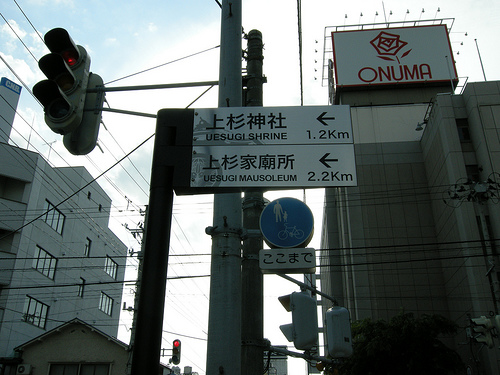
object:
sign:
[190, 105, 358, 187]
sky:
[78, 0, 207, 47]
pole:
[130, 108, 177, 375]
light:
[172, 339, 181, 365]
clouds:
[264, 1, 297, 100]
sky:
[253, 0, 495, 63]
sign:
[278, 291, 319, 350]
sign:
[261, 198, 313, 246]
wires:
[315, 239, 500, 267]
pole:
[206, 0, 240, 375]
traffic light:
[278, 291, 319, 350]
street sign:
[190, 102, 358, 187]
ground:
[145, 359, 153, 375]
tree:
[323, 307, 466, 375]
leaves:
[428, 314, 457, 336]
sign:
[358, 31, 432, 82]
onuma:
[325, 23, 464, 94]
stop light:
[33, 27, 91, 135]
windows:
[21, 198, 118, 331]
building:
[0, 77, 128, 375]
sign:
[259, 248, 316, 269]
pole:
[86, 81, 218, 93]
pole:
[102, 107, 157, 118]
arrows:
[316, 112, 335, 126]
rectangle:
[259, 248, 315, 269]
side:
[295, 298, 312, 340]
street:
[5, 227, 496, 370]